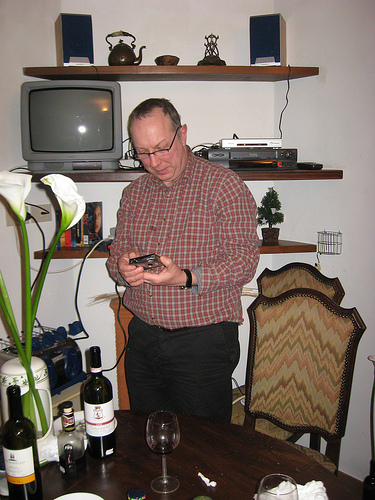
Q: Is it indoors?
A: Yes, it is indoors.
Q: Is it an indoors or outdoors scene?
A: It is indoors.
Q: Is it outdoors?
A: No, it is indoors.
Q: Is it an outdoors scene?
A: No, it is indoors.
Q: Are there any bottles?
A: Yes, there is a bottle.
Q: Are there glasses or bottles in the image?
A: Yes, there is a bottle.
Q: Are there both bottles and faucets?
A: No, there is a bottle but no faucets.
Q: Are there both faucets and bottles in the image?
A: No, there is a bottle but no faucets.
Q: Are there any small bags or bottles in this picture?
A: Yes, there is a small bottle.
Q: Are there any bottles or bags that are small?
A: Yes, the bottle is small.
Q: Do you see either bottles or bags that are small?
A: Yes, the bottle is small.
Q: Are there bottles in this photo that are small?
A: Yes, there is a small bottle.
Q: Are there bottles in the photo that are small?
A: Yes, there is a bottle that is small.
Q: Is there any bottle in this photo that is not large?
A: Yes, there is a small bottle.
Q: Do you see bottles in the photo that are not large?
A: Yes, there is a small bottle.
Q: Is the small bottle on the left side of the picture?
A: Yes, the bottle is on the left of the image.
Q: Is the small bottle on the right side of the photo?
A: No, the bottle is on the left of the image.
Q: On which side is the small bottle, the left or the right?
A: The bottle is on the left of the image.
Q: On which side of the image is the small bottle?
A: The bottle is on the left of the image.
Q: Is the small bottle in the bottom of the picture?
A: Yes, the bottle is in the bottom of the image.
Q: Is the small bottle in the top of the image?
A: No, the bottle is in the bottom of the image.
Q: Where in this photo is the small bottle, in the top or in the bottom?
A: The bottle is in the bottom of the image.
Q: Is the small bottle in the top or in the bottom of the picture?
A: The bottle is in the bottom of the image.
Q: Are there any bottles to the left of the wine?
A: Yes, there is a bottle to the left of the wine.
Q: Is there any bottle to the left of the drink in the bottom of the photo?
A: Yes, there is a bottle to the left of the wine.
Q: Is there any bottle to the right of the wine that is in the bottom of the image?
A: No, the bottle is to the left of the wine.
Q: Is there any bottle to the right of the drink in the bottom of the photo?
A: No, the bottle is to the left of the wine.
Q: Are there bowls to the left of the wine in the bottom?
A: No, there is a bottle to the left of the wine.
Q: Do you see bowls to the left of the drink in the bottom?
A: No, there is a bottle to the left of the wine.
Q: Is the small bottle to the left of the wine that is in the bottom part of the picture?
A: Yes, the bottle is to the left of the wine.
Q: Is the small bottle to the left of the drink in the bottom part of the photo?
A: Yes, the bottle is to the left of the wine.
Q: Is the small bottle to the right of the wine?
A: No, the bottle is to the left of the wine.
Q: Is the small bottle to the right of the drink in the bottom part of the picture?
A: No, the bottle is to the left of the wine.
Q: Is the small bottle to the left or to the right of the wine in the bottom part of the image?
A: The bottle is to the left of the wine.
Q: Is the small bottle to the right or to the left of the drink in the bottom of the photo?
A: The bottle is to the left of the wine.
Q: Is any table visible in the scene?
A: Yes, there is a table.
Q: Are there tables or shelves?
A: Yes, there is a table.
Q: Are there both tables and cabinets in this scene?
A: No, there is a table but no cabinets.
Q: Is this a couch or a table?
A: This is a table.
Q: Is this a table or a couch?
A: This is a table.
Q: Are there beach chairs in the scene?
A: No, there are no beach chairs.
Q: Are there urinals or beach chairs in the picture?
A: No, there are no beach chairs or urinals.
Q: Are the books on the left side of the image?
A: Yes, the books are on the left of the image.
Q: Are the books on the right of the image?
A: No, the books are on the left of the image.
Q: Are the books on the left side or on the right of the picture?
A: The books are on the left of the image.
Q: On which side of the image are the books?
A: The books are on the left of the image.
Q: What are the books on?
A: The books are on the shelf.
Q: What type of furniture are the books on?
A: The books are on the shelf.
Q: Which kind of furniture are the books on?
A: The books are on the shelf.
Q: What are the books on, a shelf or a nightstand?
A: The books are on a shelf.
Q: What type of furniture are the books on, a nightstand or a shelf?
A: The books are on a shelf.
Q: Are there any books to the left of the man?
A: Yes, there are books to the left of the man.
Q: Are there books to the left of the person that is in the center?
A: Yes, there are books to the left of the man.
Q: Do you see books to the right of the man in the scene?
A: No, the books are to the left of the man.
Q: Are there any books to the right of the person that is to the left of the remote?
A: No, the books are to the left of the man.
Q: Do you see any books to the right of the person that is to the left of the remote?
A: No, the books are to the left of the man.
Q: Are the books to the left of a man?
A: Yes, the books are to the left of a man.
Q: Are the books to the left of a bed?
A: No, the books are to the left of a man.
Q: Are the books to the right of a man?
A: No, the books are to the left of a man.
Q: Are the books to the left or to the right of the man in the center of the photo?
A: The books are to the left of the man.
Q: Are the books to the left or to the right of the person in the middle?
A: The books are to the left of the man.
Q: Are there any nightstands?
A: No, there are no nightstands.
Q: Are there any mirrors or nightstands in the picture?
A: No, there are no nightstands or mirrors.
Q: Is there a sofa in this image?
A: No, there are no sofas.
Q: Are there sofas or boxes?
A: No, there are no sofas or boxes.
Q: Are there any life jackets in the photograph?
A: No, there are no life jackets.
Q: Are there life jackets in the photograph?
A: No, there are no life jackets.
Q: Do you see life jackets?
A: No, there are no life jackets.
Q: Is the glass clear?
A: Yes, the glass is clear.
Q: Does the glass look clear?
A: Yes, the glass is clear.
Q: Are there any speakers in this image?
A: Yes, there is a speaker.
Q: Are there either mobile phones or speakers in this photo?
A: Yes, there is a speaker.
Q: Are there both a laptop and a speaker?
A: No, there is a speaker but no laptops.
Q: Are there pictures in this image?
A: No, there are no pictures.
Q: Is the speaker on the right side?
A: Yes, the speaker is on the right of the image.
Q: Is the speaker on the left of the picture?
A: No, the speaker is on the right of the image.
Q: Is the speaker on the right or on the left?
A: The speaker is on the right of the image.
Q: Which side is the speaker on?
A: The speaker is on the right of the image.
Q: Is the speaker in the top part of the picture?
A: Yes, the speaker is in the top of the image.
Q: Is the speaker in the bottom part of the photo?
A: No, the speaker is in the top of the image.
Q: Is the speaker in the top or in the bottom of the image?
A: The speaker is in the top of the image.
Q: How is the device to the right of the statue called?
A: The device is a speaker.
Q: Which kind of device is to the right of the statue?
A: The device is a speaker.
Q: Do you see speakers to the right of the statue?
A: Yes, there is a speaker to the right of the statue.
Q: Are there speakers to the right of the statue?
A: Yes, there is a speaker to the right of the statue.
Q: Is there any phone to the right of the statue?
A: No, there is a speaker to the right of the statue.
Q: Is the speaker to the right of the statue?
A: Yes, the speaker is to the right of the statue.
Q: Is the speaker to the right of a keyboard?
A: No, the speaker is to the right of the statue.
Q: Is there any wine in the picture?
A: Yes, there is wine.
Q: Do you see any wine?
A: Yes, there is wine.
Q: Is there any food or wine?
A: Yes, there is wine.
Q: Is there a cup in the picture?
A: No, there are no cups.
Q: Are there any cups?
A: No, there are no cups.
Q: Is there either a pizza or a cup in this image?
A: No, there are no cups or pizzas.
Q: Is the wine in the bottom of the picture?
A: Yes, the wine is in the bottom of the image.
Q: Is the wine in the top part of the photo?
A: No, the wine is in the bottom of the image.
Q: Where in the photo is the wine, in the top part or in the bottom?
A: The wine is in the bottom of the image.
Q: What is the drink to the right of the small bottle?
A: The drink is wine.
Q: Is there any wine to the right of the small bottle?
A: Yes, there is wine to the right of the bottle.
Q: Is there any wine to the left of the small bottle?
A: No, the wine is to the right of the bottle.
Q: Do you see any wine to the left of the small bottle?
A: No, the wine is to the right of the bottle.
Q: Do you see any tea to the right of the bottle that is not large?
A: No, there is wine to the right of the bottle.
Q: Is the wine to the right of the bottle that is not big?
A: Yes, the wine is to the right of the bottle.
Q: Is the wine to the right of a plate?
A: No, the wine is to the right of the bottle.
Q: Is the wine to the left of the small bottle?
A: No, the wine is to the right of the bottle.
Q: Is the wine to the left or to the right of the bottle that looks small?
A: The wine is to the right of the bottle.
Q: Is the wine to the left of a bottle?
A: No, the wine is to the right of a bottle.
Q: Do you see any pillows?
A: No, there are no pillows.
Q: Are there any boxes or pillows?
A: No, there are no pillows or boxes.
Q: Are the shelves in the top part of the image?
A: Yes, the shelves are in the top of the image.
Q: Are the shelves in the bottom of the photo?
A: No, the shelves are in the top of the image.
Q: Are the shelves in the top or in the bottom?
A: The shelves are in the top of the image.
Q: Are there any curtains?
A: No, there are no curtains.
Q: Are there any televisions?
A: Yes, there is a television.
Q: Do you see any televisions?
A: Yes, there is a television.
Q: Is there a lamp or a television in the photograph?
A: Yes, there is a television.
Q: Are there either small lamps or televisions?
A: Yes, there is a small television.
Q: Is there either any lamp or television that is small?
A: Yes, the television is small.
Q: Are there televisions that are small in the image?
A: Yes, there is a small television.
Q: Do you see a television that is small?
A: Yes, there is a television that is small.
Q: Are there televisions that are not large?
A: Yes, there is a small television.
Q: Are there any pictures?
A: No, there are no pictures.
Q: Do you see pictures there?
A: No, there are no pictures.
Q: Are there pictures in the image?
A: No, there are no pictures.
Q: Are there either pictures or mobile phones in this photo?
A: No, there are no pictures or mobile phones.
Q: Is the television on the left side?
A: Yes, the television is on the left of the image.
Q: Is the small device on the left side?
A: Yes, the television is on the left of the image.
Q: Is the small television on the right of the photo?
A: No, the TV is on the left of the image.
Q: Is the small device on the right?
A: No, the TV is on the left of the image.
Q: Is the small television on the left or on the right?
A: The TV is on the left of the image.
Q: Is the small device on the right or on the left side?
A: The TV is on the left of the image.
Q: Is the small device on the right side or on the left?
A: The TV is on the left of the image.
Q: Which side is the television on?
A: The television is on the left of the image.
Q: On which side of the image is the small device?
A: The television is on the left of the image.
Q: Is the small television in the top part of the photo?
A: Yes, the TV is in the top of the image.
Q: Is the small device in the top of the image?
A: Yes, the TV is in the top of the image.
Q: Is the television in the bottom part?
A: No, the television is in the top of the image.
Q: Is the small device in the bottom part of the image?
A: No, the television is in the top of the image.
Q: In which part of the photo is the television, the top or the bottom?
A: The television is in the top of the image.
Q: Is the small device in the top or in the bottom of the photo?
A: The television is in the top of the image.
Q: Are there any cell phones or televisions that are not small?
A: No, there is a television but it is small.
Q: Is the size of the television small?
A: Yes, the television is small.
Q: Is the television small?
A: Yes, the television is small.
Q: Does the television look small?
A: Yes, the television is small.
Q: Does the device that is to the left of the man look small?
A: Yes, the TV is small.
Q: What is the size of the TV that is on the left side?
A: The television is small.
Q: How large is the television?
A: The television is small.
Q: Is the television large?
A: No, the television is small.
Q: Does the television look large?
A: No, the television is small.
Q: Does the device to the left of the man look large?
A: No, the television is small.